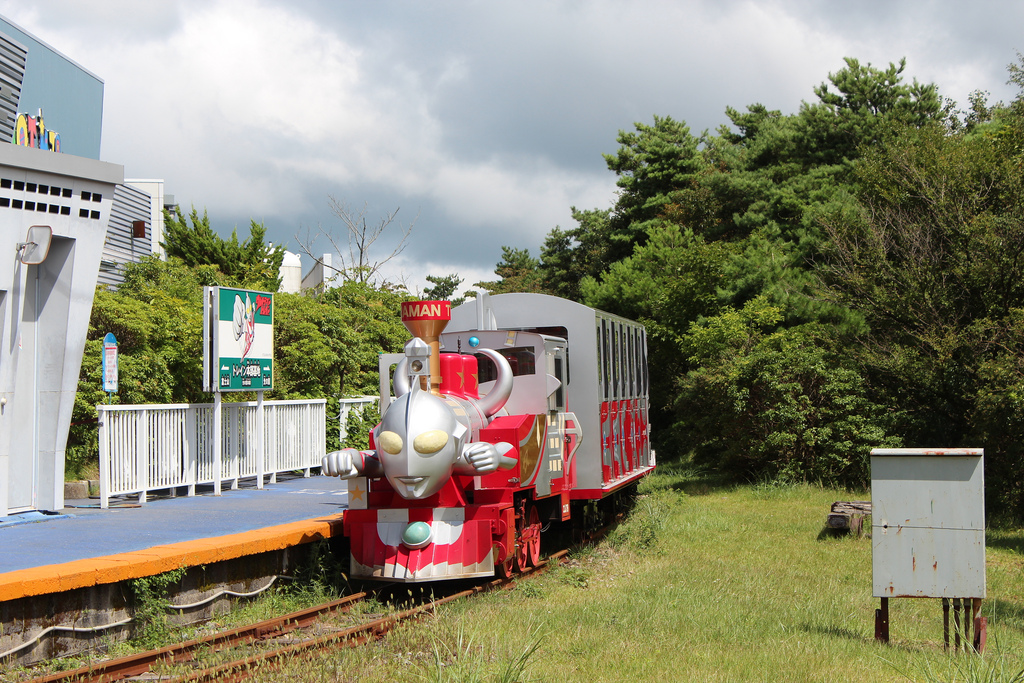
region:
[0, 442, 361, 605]
platform next to train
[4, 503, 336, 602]
yellow line painted on the platform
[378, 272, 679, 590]
red and silver train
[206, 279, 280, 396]
green and white sign on the platform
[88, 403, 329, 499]
white railing on te platform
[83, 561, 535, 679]
train tracks the train is on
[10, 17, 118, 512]
building beside the platform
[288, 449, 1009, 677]
grass beside the train tracks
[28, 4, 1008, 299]
cloud coved sky above the trees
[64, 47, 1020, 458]
trees behind the train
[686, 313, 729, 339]
green leaves on the tree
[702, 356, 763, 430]
green leaves on the tree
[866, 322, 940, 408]
green leaves on the tree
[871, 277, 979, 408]
green leaves on the tree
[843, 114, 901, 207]
green leaves on the tree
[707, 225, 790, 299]
green leaves on the tree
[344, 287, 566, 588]
a train engine shaped like an alien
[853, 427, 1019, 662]
a rusty grey metal box on thin legs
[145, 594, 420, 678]
an old pair of train tracks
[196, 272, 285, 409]
a large green and white sign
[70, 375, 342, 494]
a short metal fence painted white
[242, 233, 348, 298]
a tall white building in the distance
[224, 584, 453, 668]
a few overgrown weeds by the train tracks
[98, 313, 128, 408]
a small blue and white sign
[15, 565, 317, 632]
a cable hanging on the cement foundation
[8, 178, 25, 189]
glass window on the buidling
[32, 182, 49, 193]
glass window on the buidling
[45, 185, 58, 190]
glass window on the buidling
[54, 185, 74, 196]
glass window on the buidling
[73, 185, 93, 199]
glass window on the buidling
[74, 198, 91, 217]
glass window on the buidling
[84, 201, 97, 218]
glass window on the buidling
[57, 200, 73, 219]
glass window on the buidling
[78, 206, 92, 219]
A window on a building.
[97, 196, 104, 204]
A window on a building.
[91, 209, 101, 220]
A window on a building.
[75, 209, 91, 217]
A window on a building.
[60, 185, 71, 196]
A window on a building.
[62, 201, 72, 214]
A window on a building.